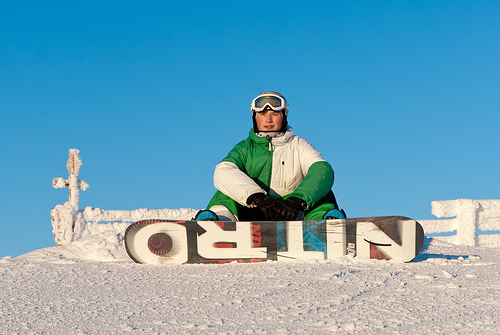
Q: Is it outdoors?
A: Yes, it is outdoors.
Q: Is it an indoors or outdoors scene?
A: It is outdoors.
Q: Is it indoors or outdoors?
A: It is outdoors.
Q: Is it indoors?
A: No, it is outdoors.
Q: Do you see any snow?
A: Yes, there is snow.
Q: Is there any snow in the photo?
A: Yes, there is snow.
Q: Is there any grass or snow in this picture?
A: Yes, there is snow.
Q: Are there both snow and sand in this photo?
A: No, there is snow but no sand.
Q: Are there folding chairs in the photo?
A: No, there are no folding chairs.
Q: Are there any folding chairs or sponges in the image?
A: No, there are no folding chairs or sponges.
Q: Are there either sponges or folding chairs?
A: No, there are no folding chairs or sponges.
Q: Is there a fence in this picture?
A: Yes, there is a fence.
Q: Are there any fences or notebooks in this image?
A: Yes, there is a fence.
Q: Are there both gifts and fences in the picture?
A: No, there is a fence but no gifts.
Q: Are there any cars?
A: No, there are no cars.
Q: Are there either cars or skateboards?
A: No, there are no cars or skateboards.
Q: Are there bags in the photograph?
A: No, there are no bags.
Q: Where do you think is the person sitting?
A: The person is sitting on the hill.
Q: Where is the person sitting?
A: The person is sitting on the hill.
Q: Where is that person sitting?
A: The person is sitting in the snow.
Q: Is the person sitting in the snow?
A: Yes, the person is sitting in the snow.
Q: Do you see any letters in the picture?
A: Yes, there are letters.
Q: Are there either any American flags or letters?
A: Yes, there are letters.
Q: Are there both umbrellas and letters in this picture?
A: No, there are letters but no umbrellas.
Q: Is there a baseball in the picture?
A: No, there are no baseballs.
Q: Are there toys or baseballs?
A: No, there are no baseballs or toys.